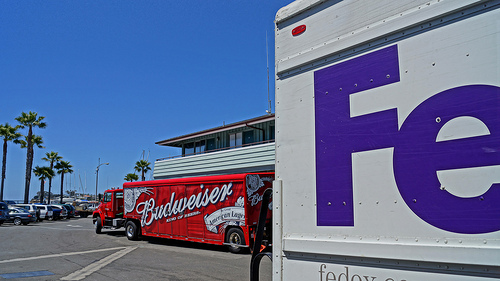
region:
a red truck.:
[94, 170, 275, 245]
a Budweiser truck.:
[92, 170, 279, 247]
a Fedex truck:
[247, 1, 495, 278]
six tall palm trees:
[1, 108, 67, 200]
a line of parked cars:
[0, 194, 89, 226]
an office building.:
[155, 113, 275, 157]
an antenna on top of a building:
[259, 12, 276, 114]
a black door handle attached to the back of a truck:
[249, 182, 273, 279]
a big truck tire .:
[123, 217, 138, 240]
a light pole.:
[93, 159, 108, 199]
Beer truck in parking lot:
[87, 176, 273, 248]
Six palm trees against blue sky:
[2, 105, 74, 198]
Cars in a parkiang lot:
[2, 199, 99, 222]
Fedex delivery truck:
[268, 6, 498, 273]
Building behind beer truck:
[149, 113, 276, 168]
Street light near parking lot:
[89, 145, 116, 207]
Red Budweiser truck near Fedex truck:
[87, 177, 272, 252]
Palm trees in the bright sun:
[2, 105, 83, 199]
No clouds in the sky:
[2, 7, 263, 115]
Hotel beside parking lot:
[157, 118, 274, 164]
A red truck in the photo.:
[88, 173, 264, 248]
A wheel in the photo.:
[225, 224, 248, 255]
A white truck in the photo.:
[274, 0, 496, 280]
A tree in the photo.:
[18, 104, 40, 199]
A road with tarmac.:
[140, 248, 207, 278]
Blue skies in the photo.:
[62, 17, 251, 90]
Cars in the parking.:
[4, 199, 60, 222]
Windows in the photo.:
[227, 128, 259, 143]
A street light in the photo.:
[83, 152, 110, 202]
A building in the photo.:
[154, 112, 276, 174]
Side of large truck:
[275, 10, 495, 277]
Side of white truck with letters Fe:
[288, 35, 498, 260]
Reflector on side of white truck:
[276, 7, 316, 44]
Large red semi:
[85, 170, 265, 250]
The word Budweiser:
[125, 175, 247, 226]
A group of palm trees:
[1, 108, 81, 193]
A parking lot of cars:
[10, 186, 80, 222]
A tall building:
[146, 111, 273, 162]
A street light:
[86, 150, 113, 171]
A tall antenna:
[255, 29, 275, 114]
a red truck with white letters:
[85, 163, 275, 255]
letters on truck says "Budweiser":
[119, 176, 248, 240]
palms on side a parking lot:
[1, 105, 75, 203]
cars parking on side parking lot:
[4, 192, 93, 222]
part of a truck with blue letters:
[271, 0, 498, 277]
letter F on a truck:
[296, 42, 405, 239]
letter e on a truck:
[390, 79, 498, 237]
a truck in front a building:
[85, 108, 279, 257]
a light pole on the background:
[89, 152, 116, 199]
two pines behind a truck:
[89, 149, 156, 243]